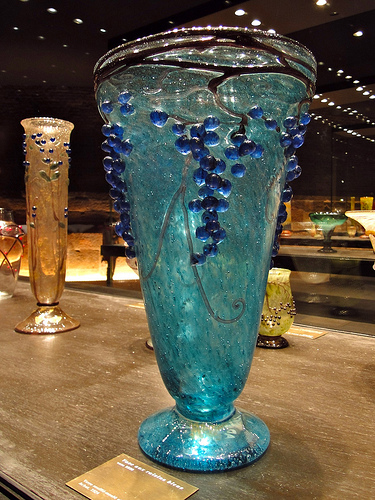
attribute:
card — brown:
[58, 445, 220, 499]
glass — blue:
[89, 28, 309, 475]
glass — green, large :
[305, 207, 350, 255]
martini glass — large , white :
[344, 208, 374, 269]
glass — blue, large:
[95, 27, 330, 471]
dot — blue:
[189, 253, 205, 269]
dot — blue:
[216, 198, 227, 212]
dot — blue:
[249, 105, 265, 118]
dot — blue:
[149, 109, 168, 127]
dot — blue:
[281, 188, 289, 201]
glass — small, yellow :
[262, 263, 298, 350]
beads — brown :
[267, 305, 283, 326]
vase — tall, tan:
[77, 41, 291, 457]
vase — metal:
[82, 26, 309, 474]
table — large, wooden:
[3, 276, 372, 498]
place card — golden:
[64, 452, 194, 498]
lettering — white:
[115, 455, 184, 490]